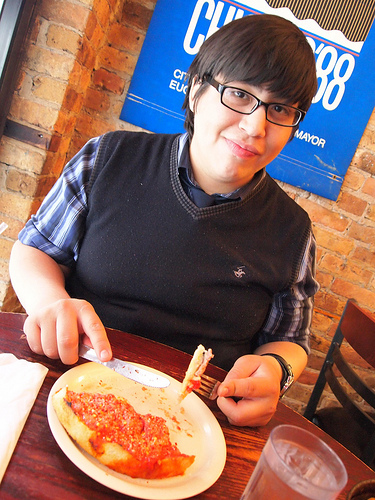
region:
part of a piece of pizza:
[52, 387, 191, 478]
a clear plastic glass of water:
[237, 423, 346, 498]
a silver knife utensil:
[75, 341, 168, 387]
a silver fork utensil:
[194, 373, 222, 400]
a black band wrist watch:
[260, 349, 295, 404]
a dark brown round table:
[0, 310, 374, 496]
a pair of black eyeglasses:
[202, 71, 305, 129]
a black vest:
[61, 124, 309, 373]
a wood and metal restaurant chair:
[294, 299, 374, 476]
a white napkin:
[1, 351, 47, 498]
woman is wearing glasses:
[197, 57, 312, 125]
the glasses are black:
[182, 52, 302, 138]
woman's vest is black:
[79, 104, 319, 385]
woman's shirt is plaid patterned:
[38, 152, 333, 338]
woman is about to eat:
[7, 2, 360, 410]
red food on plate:
[64, 362, 220, 486]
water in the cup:
[257, 417, 345, 498]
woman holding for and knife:
[36, 270, 298, 437]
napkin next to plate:
[0, 330, 85, 496]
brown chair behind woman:
[314, 259, 374, 487]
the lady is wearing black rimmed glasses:
[207, 73, 306, 128]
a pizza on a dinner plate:
[51, 385, 196, 479]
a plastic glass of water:
[239, 423, 347, 498]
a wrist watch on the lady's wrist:
[262, 350, 295, 401]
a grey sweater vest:
[87, 132, 309, 368]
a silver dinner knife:
[76, 344, 171, 387]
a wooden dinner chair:
[306, 297, 374, 465]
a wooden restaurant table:
[111, 323, 192, 369]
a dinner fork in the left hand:
[189, 371, 223, 399]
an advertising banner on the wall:
[312, 22, 374, 199]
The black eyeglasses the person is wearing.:
[209, 77, 304, 131]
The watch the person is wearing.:
[268, 353, 298, 393]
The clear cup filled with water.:
[252, 420, 350, 499]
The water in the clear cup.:
[258, 436, 335, 499]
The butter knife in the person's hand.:
[88, 338, 168, 392]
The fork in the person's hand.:
[196, 366, 223, 401]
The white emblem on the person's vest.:
[228, 260, 243, 277]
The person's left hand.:
[20, 296, 110, 364]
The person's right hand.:
[220, 353, 277, 429]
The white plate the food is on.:
[54, 347, 229, 499]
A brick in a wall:
[3, 117, 60, 154]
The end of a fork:
[191, 372, 222, 402]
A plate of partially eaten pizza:
[44, 357, 228, 499]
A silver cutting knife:
[75, 343, 170, 389]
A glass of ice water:
[239, 423, 348, 498]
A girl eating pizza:
[7, 13, 317, 429]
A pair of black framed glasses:
[202, 69, 304, 129]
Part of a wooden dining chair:
[304, 298, 374, 473]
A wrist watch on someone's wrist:
[259, 352, 294, 400]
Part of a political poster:
[119, 0, 374, 201]